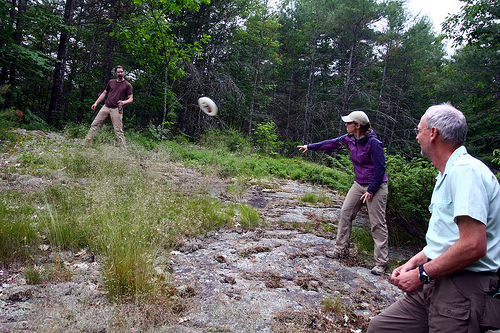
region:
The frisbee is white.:
[196, 92, 216, 122]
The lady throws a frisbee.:
[294, 86, 398, 271]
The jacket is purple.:
[303, 132, 390, 187]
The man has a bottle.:
[116, 99, 128, 114]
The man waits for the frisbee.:
[85, 55, 129, 150]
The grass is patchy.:
[2, 195, 177, 310]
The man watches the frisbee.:
[391, 100, 499, 331]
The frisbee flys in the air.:
[196, 93, 226, 122]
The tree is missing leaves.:
[281, 54, 412, 156]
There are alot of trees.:
[13, 1, 488, 141]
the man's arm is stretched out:
[292, 94, 391, 281]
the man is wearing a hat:
[327, 104, 387, 144]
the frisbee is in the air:
[179, 84, 248, 147]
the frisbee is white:
[172, 80, 235, 133]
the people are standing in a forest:
[73, 37, 487, 316]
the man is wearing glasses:
[408, 110, 439, 140]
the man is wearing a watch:
[407, 261, 444, 294]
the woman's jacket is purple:
[318, 118, 408, 205]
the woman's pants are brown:
[331, 180, 393, 271]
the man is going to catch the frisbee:
[79, 42, 254, 197]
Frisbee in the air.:
[200, 93, 220, 119]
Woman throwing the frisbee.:
[291, 105, 393, 274]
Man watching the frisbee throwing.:
[368, 105, 495, 328]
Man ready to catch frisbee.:
[79, 64, 132, 147]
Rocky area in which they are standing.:
[3, 126, 426, 332]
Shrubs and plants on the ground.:
[4, 107, 499, 290]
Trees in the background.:
[1, 7, 498, 158]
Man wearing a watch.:
[413, 263, 436, 285]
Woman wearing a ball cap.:
[341, 111, 371, 133]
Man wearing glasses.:
[416, 124, 443, 134]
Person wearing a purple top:
[287, 109, 404, 277]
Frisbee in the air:
[181, 82, 253, 128]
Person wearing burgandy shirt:
[76, 50, 147, 146]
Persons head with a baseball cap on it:
[330, 102, 380, 144]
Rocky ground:
[200, 239, 312, 313]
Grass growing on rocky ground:
[79, 178, 187, 307]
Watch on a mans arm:
[392, 255, 455, 294]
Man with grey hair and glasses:
[402, 93, 498, 225]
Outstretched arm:
[290, 124, 349, 166]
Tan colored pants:
[73, 105, 138, 149]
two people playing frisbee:
[86, 58, 409, 280]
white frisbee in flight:
[196, 86, 222, 121]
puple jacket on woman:
[316, 129, 393, 190]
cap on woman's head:
[333, 103, 375, 134]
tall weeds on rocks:
[81, 219, 228, 311]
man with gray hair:
[391, 101, 496, 316]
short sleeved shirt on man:
[419, 147, 494, 272]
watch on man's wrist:
[406, 259, 434, 288]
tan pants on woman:
[326, 180, 398, 270]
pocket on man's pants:
[426, 296, 472, 331]